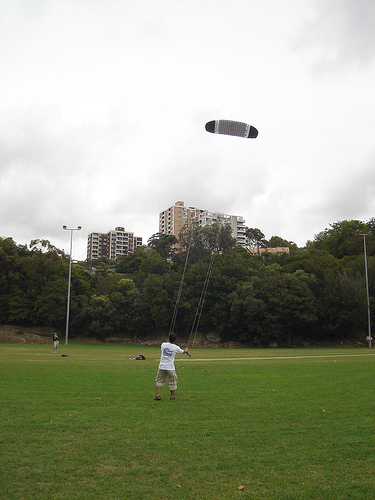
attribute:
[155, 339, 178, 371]
shirt — white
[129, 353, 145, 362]
person lying — laying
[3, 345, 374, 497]
grass — green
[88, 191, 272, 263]
buildings — tall, varied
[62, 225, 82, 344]
light pole — tall, white, silver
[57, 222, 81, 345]
street light — tall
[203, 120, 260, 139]
kite — black , grey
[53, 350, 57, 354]
shoe — white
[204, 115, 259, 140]
kite — black, wide, long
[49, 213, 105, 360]
pole — large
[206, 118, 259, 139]
kite — black, white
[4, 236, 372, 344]
tree — dense, green, tall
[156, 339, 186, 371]
t-shirt — white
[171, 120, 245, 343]
kite — large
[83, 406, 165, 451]
grass — short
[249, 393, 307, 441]
grass — short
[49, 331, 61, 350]
woman — small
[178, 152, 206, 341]
strings — white